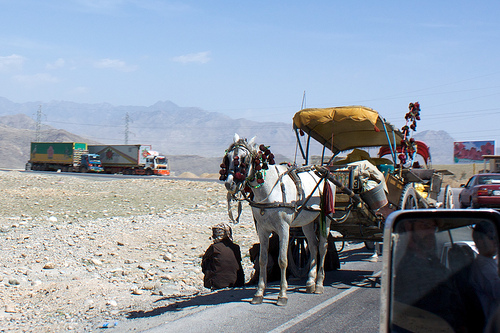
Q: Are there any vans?
A: No, there are no vans.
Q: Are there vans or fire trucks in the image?
A: No, there are no vans or fire trucks.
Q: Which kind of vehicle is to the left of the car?
A: The vehicle is a wagon.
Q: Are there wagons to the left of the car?
A: Yes, there is a wagon to the left of the car.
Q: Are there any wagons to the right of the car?
A: No, the wagon is to the left of the car.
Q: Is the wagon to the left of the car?
A: Yes, the wagon is to the left of the car.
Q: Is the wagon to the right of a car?
A: No, the wagon is to the left of a car.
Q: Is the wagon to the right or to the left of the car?
A: The wagon is to the left of the car.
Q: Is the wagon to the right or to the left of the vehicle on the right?
A: The wagon is to the left of the car.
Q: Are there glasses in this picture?
A: No, there are no glasses.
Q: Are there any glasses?
A: No, there are no glasses.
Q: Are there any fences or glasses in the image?
A: No, there are no glasses or fences.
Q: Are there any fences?
A: No, there are no fences.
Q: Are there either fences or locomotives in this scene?
A: No, there are no fences or locomotives.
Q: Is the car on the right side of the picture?
A: Yes, the car is on the right of the image.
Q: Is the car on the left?
A: No, the car is on the right of the image.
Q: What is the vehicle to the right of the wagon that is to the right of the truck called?
A: The vehicle is a car.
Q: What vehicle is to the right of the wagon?
A: The vehicle is a car.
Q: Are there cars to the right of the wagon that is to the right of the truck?
A: Yes, there is a car to the right of the wagon.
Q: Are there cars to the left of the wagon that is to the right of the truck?
A: No, the car is to the right of the wagon.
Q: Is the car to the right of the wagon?
A: Yes, the car is to the right of the wagon.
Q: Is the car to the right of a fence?
A: No, the car is to the right of the wagon.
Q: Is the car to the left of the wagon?
A: No, the car is to the right of the wagon.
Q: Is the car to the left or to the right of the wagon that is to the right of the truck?
A: The car is to the right of the wagon.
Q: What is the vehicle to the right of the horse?
A: The vehicle is a car.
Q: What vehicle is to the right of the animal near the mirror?
A: The vehicle is a car.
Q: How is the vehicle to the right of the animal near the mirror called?
A: The vehicle is a car.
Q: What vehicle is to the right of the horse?
A: The vehicle is a car.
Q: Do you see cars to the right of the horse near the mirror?
A: Yes, there is a car to the right of the horse.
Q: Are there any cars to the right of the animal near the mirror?
A: Yes, there is a car to the right of the horse.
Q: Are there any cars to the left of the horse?
A: No, the car is to the right of the horse.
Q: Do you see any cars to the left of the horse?
A: No, the car is to the right of the horse.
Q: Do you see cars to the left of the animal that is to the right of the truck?
A: No, the car is to the right of the horse.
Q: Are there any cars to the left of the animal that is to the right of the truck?
A: No, the car is to the right of the horse.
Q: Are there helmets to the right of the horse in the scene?
A: No, there is a car to the right of the horse.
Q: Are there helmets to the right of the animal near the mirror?
A: No, there is a car to the right of the horse.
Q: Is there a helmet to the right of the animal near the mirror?
A: No, there is a car to the right of the horse.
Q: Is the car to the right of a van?
A: No, the car is to the right of the horse.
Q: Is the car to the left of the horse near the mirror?
A: No, the car is to the right of the horse.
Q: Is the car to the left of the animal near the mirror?
A: No, the car is to the right of the horse.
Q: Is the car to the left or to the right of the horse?
A: The car is to the right of the horse.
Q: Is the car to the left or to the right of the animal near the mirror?
A: The car is to the right of the horse.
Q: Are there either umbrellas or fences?
A: No, there are no fences or umbrellas.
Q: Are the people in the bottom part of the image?
A: Yes, the people are in the bottom of the image.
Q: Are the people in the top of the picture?
A: No, the people are in the bottom of the image.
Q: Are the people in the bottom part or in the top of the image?
A: The people are in the bottom of the image.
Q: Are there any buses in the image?
A: No, there are no buses.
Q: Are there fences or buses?
A: No, there are no buses or fences.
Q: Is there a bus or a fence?
A: No, there are no buses or fences.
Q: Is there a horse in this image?
A: Yes, there is a horse.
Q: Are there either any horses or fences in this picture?
A: Yes, there is a horse.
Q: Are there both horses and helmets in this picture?
A: No, there is a horse but no helmets.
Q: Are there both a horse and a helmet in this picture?
A: No, there is a horse but no helmets.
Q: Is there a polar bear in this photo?
A: No, there are no polar bears.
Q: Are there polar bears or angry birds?
A: No, there are no polar bears or angry birds.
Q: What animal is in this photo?
A: The animal is a horse.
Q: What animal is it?
A: The animal is a horse.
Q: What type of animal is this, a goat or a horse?
A: This is a horse.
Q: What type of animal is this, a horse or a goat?
A: This is a horse.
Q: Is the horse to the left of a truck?
A: No, the horse is to the right of a truck.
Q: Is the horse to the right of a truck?
A: Yes, the horse is to the right of a truck.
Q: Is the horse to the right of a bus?
A: No, the horse is to the right of a truck.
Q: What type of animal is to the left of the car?
A: The animal is a horse.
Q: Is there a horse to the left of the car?
A: Yes, there is a horse to the left of the car.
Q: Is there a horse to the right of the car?
A: No, the horse is to the left of the car.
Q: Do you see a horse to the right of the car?
A: No, the horse is to the left of the car.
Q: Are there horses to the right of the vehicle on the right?
A: No, the horse is to the left of the car.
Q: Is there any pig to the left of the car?
A: No, there is a horse to the left of the car.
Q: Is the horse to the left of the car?
A: Yes, the horse is to the left of the car.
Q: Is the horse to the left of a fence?
A: No, the horse is to the left of the car.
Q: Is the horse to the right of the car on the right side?
A: No, the horse is to the left of the car.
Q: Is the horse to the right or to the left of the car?
A: The horse is to the left of the car.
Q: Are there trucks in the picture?
A: Yes, there is a truck.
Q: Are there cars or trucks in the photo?
A: Yes, there is a truck.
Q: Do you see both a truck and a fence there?
A: No, there is a truck but no fences.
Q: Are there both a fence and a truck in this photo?
A: No, there is a truck but no fences.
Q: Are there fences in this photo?
A: No, there are no fences.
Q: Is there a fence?
A: No, there are no fences.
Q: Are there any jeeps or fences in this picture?
A: No, there are no fences or jeeps.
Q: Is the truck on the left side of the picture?
A: Yes, the truck is on the left of the image.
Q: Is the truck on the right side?
A: No, the truck is on the left of the image.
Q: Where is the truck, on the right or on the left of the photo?
A: The truck is on the left of the image.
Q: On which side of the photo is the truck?
A: The truck is on the left of the image.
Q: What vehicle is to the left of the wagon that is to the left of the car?
A: The vehicle is a truck.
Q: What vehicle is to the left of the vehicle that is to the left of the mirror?
A: The vehicle is a truck.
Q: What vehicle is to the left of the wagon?
A: The vehicle is a truck.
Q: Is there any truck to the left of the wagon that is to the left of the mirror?
A: Yes, there is a truck to the left of the wagon.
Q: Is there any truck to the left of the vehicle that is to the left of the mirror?
A: Yes, there is a truck to the left of the wagon.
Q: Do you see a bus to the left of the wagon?
A: No, there is a truck to the left of the wagon.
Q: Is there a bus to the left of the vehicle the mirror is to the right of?
A: No, there is a truck to the left of the wagon.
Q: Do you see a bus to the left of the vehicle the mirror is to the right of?
A: No, there is a truck to the left of the wagon.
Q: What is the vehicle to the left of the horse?
A: The vehicle is a truck.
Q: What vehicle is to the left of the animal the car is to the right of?
A: The vehicle is a truck.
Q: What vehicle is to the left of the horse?
A: The vehicle is a truck.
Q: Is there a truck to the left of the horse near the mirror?
A: Yes, there is a truck to the left of the horse.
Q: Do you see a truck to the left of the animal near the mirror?
A: Yes, there is a truck to the left of the horse.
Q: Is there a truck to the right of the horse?
A: No, the truck is to the left of the horse.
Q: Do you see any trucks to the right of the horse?
A: No, the truck is to the left of the horse.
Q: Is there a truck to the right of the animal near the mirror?
A: No, the truck is to the left of the horse.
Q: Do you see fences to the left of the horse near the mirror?
A: No, there is a truck to the left of the horse.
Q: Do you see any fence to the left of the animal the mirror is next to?
A: No, there is a truck to the left of the horse.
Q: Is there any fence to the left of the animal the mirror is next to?
A: No, there is a truck to the left of the horse.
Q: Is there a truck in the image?
A: Yes, there is a truck.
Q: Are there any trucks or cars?
A: Yes, there is a truck.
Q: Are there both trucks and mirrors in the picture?
A: Yes, there are both a truck and a mirror.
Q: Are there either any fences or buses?
A: No, there are no fences or buses.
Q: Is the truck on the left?
A: Yes, the truck is on the left of the image.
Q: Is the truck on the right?
A: No, the truck is on the left of the image.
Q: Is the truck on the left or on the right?
A: The truck is on the left of the image.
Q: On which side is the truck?
A: The truck is on the left of the image.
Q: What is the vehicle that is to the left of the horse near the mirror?
A: The vehicle is a truck.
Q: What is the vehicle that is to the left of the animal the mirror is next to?
A: The vehicle is a truck.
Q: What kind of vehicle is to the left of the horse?
A: The vehicle is a truck.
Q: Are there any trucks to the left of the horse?
A: Yes, there is a truck to the left of the horse.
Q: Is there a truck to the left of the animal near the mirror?
A: Yes, there is a truck to the left of the horse.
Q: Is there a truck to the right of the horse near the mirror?
A: No, the truck is to the left of the horse.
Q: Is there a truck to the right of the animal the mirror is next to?
A: No, the truck is to the left of the horse.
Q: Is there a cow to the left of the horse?
A: No, there is a truck to the left of the horse.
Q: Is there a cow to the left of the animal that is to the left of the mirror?
A: No, there is a truck to the left of the horse.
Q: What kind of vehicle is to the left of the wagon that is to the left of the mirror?
A: The vehicle is a truck.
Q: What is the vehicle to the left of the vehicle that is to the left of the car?
A: The vehicle is a truck.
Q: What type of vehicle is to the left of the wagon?
A: The vehicle is a truck.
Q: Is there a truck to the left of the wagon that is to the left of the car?
A: Yes, there is a truck to the left of the wagon.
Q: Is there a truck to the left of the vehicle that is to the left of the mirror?
A: Yes, there is a truck to the left of the wagon.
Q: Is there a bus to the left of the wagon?
A: No, there is a truck to the left of the wagon.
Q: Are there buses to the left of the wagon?
A: No, there is a truck to the left of the wagon.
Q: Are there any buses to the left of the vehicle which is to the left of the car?
A: No, there is a truck to the left of the wagon.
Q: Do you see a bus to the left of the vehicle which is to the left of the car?
A: No, there is a truck to the left of the wagon.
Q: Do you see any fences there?
A: No, there are no fences.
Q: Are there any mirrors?
A: Yes, there is a mirror.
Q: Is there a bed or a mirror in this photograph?
A: Yes, there is a mirror.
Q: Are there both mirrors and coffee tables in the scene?
A: No, there is a mirror but no coffee tables.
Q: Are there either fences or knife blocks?
A: No, there are no fences or knife blocks.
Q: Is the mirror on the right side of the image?
A: Yes, the mirror is on the right of the image.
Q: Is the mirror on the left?
A: No, the mirror is on the right of the image.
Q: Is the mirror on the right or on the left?
A: The mirror is on the right of the image.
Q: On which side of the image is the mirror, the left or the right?
A: The mirror is on the right of the image.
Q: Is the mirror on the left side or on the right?
A: The mirror is on the right of the image.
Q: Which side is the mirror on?
A: The mirror is on the right of the image.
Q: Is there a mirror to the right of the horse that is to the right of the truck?
A: Yes, there is a mirror to the right of the horse.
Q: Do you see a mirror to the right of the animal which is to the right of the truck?
A: Yes, there is a mirror to the right of the horse.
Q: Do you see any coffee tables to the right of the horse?
A: No, there is a mirror to the right of the horse.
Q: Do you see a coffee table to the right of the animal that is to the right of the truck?
A: No, there is a mirror to the right of the horse.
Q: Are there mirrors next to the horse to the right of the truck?
A: Yes, there is a mirror next to the horse.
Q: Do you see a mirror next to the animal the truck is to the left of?
A: Yes, there is a mirror next to the horse.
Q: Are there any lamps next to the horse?
A: No, there is a mirror next to the horse.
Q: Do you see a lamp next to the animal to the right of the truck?
A: No, there is a mirror next to the horse.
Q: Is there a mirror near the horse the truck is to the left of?
A: Yes, there is a mirror near the horse.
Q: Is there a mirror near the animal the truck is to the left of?
A: Yes, there is a mirror near the horse.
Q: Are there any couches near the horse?
A: No, there is a mirror near the horse.